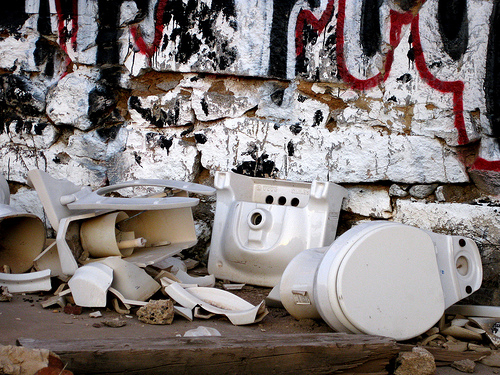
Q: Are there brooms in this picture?
A: No, there are no brooms.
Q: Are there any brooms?
A: No, there are no brooms.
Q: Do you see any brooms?
A: No, there are no brooms.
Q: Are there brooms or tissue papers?
A: No, there are no brooms or tissue papers.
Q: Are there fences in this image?
A: No, there are no fences.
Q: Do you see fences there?
A: No, there are no fences.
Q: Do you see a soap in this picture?
A: No, there are no soaps.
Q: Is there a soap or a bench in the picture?
A: No, there are no soaps or benches.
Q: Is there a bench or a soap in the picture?
A: No, there are no soaps or benches.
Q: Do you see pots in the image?
A: No, there are no pots.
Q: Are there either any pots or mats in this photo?
A: No, there are no pots or mats.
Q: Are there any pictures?
A: No, there are no pictures.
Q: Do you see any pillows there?
A: No, there are no pillows.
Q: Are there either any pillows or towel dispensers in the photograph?
A: No, there are no pillows or towel dispensers.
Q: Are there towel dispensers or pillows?
A: No, there are no pillows or towel dispensers.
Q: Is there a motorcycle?
A: No, there are no motorcycles.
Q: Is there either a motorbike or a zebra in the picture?
A: No, there are no motorcycles or zebras.